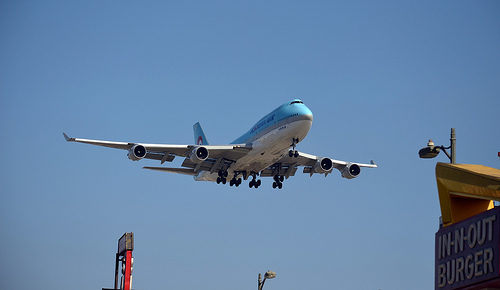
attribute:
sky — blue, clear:
[119, 23, 173, 60]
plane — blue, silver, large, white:
[50, 87, 383, 200]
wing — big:
[68, 118, 190, 156]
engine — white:
[128, 139, 156, 160]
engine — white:
[180, 150, 218, 171]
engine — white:
[311, 152, 333, 172]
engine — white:
[340, 160, 362, 185]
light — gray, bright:
[415, 119, 458, 160]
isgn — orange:
[104, 227, 137, 288]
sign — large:
[424, 161, 496, 283]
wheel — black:
[212, 169, 229, 186]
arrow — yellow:
[435, 157, 488, 211]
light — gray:
[255, 259, 273, 280]